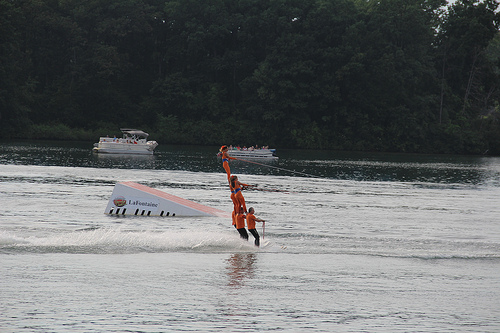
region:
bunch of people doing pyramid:
[208, 138, 283, 262]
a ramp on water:
[101, 182, 243, 230]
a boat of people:
[90, 120, 160, 157]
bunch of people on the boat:
[89, 116, 166, 158]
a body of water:
[315, 225, 490, 284]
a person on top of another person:
[214, 138, 236, 189]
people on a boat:
[212, 139, 282, 161]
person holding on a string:
[200, 132, 497, 217]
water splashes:
[24, 216, 238, 261]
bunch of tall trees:
[19, 13, 493, 120]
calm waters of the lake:
[161, 272, 391, 314]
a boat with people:
[96, 131, 158, 153]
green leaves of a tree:
[349, 20, 396, 80]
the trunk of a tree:
[463, 76, 473, 108]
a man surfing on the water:
[248, 206, 271, 249]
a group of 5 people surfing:
[221, 144, 262, 244]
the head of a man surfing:
[247, 207, 255, 215]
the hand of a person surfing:
[253, 217, 269, 222]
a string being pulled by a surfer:
[247, 160, 291, 170]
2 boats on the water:
[96, 130, 281, 162]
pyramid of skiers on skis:
[216, 141, 270, 250]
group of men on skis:
[221, 207, 272, 252]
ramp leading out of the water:
[96, 174, 228, 229]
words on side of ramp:
[124, 197, 160, 211]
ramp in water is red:
[115, 178, 223, 219]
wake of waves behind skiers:
[0, 218, 265, 256]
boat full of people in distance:
[220, 143, 278, 159]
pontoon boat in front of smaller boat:
[86, 118, 162, 160]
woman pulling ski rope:
[229, 152, 370, 193]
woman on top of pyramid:
[215, 142, 242, 184]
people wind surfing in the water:
[216, 136, 273, 253]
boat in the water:
[84, 115, 164, 163]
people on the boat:
[224, 135, 278, 160]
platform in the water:
[92, 170, 212, 225]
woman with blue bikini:
[217, 143, 234, 175]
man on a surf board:
[245, 205, 270, 247]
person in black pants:
[234, 203, 247, 239]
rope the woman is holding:
[237, 152, 304, 180]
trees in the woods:
[275, 28, 415, 111]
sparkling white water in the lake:
[323, 155, 402, 177]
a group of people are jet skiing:
[208, 137, 276, 257]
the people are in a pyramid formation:
[210, 135, 280, 261]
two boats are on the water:
[93, 126, 287, 168]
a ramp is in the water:
[99, 168, 220, 238]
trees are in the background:
[13, 9, 491, 146]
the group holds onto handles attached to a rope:
[214, 139, 493, 245]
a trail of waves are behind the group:
[31, 220, 235, 250]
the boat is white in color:
[86, 128, 161, 160]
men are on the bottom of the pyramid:
[228, 205, 270, 246]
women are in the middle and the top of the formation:
[215, 140, 249, 207]